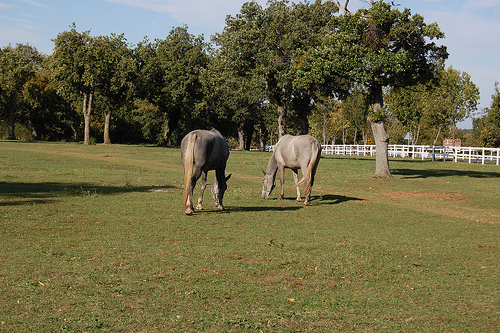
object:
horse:
[260, 134, 323, 206]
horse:
[180, 127, 232, 215]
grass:
[3, 144, 94, 218]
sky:
[0, 1, 500, 97]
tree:
[45, 22, 117, 144]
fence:
[267, 143, 499, 165]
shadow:
[2, 176, 179, 205]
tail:
[305, 138, 321, 195]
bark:
[377, 144, 384, 158]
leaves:
[89, 51, 101, 61]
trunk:
[81, 94, 92, 144]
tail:
[182, 133, 196, 205]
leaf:
[285, 295, 297, 303]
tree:
[216, 1, 337, 161]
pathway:
[318, 182, 427, 209]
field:
[2, 139, 499, 332]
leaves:
[268, 24, 289, 41]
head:
[260, 171, 275, 200]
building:
[443, 137, 462, 147]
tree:
[292, 2, 451, 179]